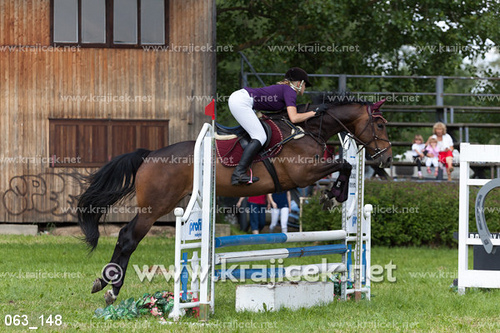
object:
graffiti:
[0, 162, 111, 216]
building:
[2, 2, 219, 223]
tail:
[76, 148, 151, 256]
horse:
[76, 98, 392, 305]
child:
[426, 138, 440, 176]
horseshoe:
[475, 178, 500, 254]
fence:
[455, 139, 500, 299]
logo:
[61, 204, 153, 213]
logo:
[132, 258, 397, 282]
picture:
[6, 1, 500, 331]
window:
[49, 0, 169, 47]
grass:
[5, 233, 500, 328]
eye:
[378, 123, 384, 128]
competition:
[5, 5, 498, 329]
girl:
[228, 67, 329, 185]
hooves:
[336, 190, 348, 202]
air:
[7, 8, 500, 322]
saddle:
[215, 119, 272, 185]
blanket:
[214, 114, 283, 166]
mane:
[297, 100, 374, 111]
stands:
[242, 64, 500, 194]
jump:
[67, 62, 402, 317]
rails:
[215, 262, 345, 279]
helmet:
[285, 67, 313, 87]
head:
[285, 67, 308, 95]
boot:
[231, 139, 261, 186]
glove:
[313, 104, 329, 117]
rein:
[305, 103, 392, 158]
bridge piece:
[366, 138, 391, 158]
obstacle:
[167, 122, 372, 321]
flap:
[166, 122, 214, 321]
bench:
[393, 162, 482, 181]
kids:
[412, 135, 427, 179]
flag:
[205, 99, 215, 120]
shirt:
[244, 84, 298, 111]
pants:
[228, 88, 268, 146]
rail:
[214, 244, 346, 264]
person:
[427, 122, 455, 181]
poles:
[215, 229, 347, 247]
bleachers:
[241, 53, 499, 174]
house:
[3, 4, 219, 219]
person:
[267, 191, 291, 233]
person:
[236, 195, 271, 235]